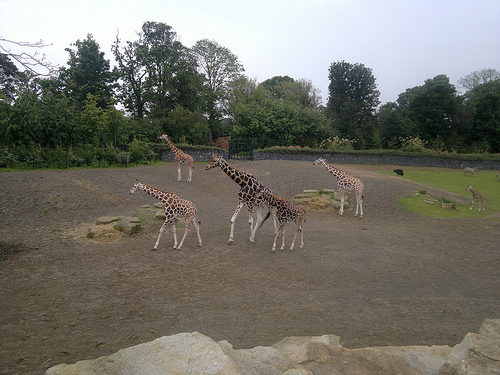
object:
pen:
[0, 138, 500, 375]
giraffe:
[129, 177, 204, 251]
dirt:
[0, 160, 499, 374]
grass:
[357, 170, 500, 220]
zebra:
[463, 165, 478, 177]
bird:
[392, 168, 405, 179]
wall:
[44, 316, 500, 375]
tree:
[54, 31, 122, 111]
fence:
[160, 144, 230, 161]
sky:
[0, 0, 500, 123]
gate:
[229, 139, 254, 161]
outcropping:
[0, 177, 132, 217]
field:
[0, 161, 500, 375]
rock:
[465, 315, 499, 361]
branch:
[140, 69, 150, 79]